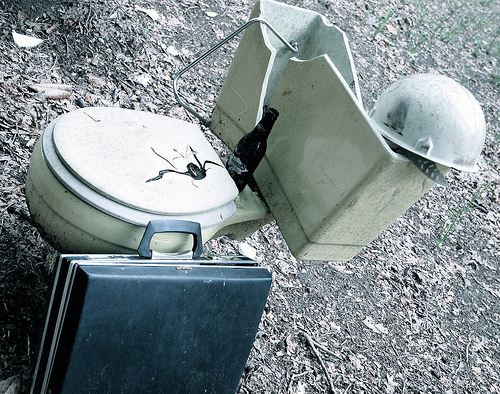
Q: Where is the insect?
A: On the white block.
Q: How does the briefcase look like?
A: It is black.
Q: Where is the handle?
A: On the briefcase.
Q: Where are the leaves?
A: On the ground.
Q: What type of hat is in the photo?
A: Helmet.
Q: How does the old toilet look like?
A: White.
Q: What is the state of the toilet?
A: Broken.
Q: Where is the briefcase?
A: On the ground.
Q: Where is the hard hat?
A: In the toilet tank.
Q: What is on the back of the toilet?
A: A hat.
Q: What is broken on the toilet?
A: The back.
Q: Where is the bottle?
A: On the toilet.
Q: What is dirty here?
A: The toilet.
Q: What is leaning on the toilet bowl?
A: A briefcase.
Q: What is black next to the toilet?
A: The briefcase.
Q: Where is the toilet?
A: On the ground.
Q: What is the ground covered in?
A: Leaves.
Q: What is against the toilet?
A: A briefcase.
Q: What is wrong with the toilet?
A: It is broken.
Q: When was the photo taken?
A: Daytime.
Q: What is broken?
A: Toilet.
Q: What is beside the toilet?
A: Suitcase.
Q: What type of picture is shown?
A: Black and white.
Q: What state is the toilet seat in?
A: Down.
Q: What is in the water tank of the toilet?
A: Globe.